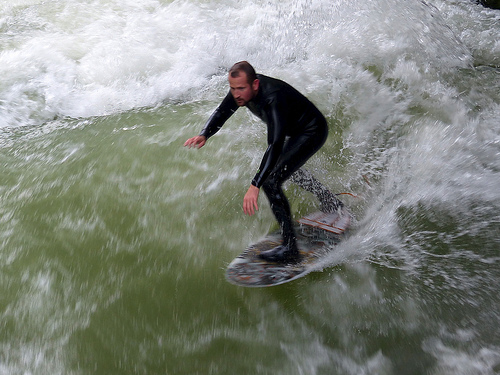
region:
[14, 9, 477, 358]
a man surfing a wave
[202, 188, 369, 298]
a patterned surfboard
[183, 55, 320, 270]
a man in a shiny black wetsuit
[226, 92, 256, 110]
a brown goatee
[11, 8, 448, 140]
white foam from crashing wave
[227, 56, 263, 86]
short brown hair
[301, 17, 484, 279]
a crashing wave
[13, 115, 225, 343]
clear green water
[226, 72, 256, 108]
a man with a serious concentrating face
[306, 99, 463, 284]
splashing water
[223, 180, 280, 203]
left hand of surfer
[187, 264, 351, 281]
tip of surfboard in water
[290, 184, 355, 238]
logo of surfboard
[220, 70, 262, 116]
facial expression of surfer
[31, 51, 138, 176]
waves ridden by surfer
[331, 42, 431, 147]
waves of ocean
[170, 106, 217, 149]
right hand of surfer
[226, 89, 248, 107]
surfers beard on his face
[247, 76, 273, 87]
left ear of surfer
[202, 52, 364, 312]
surfer riding the waves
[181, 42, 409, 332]
the man is surfing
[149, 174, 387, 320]
surfboard is on the water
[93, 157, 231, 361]
the water is green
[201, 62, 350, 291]
man is on the surfboard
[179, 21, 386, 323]
the man is wearing a wet suit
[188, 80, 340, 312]
the wet suit is black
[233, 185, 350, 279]
the shoes are black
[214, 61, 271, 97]
the hair is brown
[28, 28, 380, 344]
the water is not calm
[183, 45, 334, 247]
the man is white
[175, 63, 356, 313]
a man surfing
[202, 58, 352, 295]
a man in a black wet suit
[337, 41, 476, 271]
the waves behind the surfer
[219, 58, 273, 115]
the surfers face looks concetrated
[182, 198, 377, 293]
a surf board with a cool design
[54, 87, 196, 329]
what appears to be a lake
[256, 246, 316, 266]
the surfers feet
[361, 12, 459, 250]
some awesome waves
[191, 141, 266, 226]
the surfers hands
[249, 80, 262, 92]
the surfers ear that is wet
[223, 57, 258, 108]
the head of a person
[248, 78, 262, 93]
the ear of a person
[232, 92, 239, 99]
the nose of a person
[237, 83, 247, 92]
the eye of a person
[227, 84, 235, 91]
the eye of a person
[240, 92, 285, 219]
the hand of a person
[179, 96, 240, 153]
the hand of a person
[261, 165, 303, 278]
the leg of a person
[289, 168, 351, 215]
the leg of a person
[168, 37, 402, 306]
a person surfing